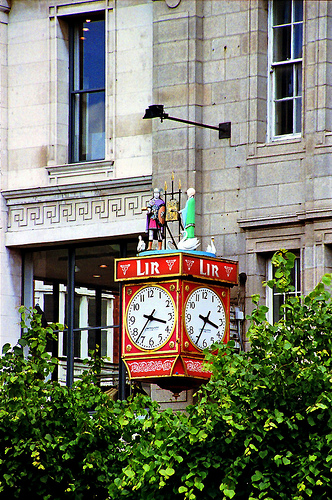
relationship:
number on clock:
[165, 310, 174, 320] [105, 242, 246, 409]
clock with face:
[116, 282, 233, 358] [112, 244, 238, 386]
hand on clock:
[143, 313, 167, 324] [123, 286, 179, 350]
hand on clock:
[134, 308, 153, 343] [123, 286, 179, 350]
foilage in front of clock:
[207, 337, 304, 423] [94, 264, 208, 339]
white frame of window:
[264, 259, 276, 335] [250, 243, 308, 362]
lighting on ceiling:
[96, 261, 106, 268] [75, 257, 111, 289]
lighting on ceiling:
[93, 272, 101, 277] [75, 257, 111, 289]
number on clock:
[202, 291, 209, 300] [123, 286, 179, 350]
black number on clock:
[164, 311, 173, 321] [123, 286, 179, 350]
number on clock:
[131, 301, 140, 311] [123, 286, 179, 350]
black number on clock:
[139, 291, 148, 305] [123, 286, 179, 350]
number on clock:
[188, 325, 194, 333] [183, 286, 226, 350]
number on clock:
[202, 291, 209, 300] [183, 282, 228, 359]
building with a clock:
[151, 6, 331, 405] [117, 246, 239, 377]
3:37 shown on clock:
[123, 287, 168, 345] [115, 246, 235, 399]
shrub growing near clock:
[1, 303, 66, 414] [112, 170, 239, 398]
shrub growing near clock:
[109, 407, 212, 498] [112, 170, 239, 398]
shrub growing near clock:
[184, 246, 321, 436] [112, 170, 239, 398]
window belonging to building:
[42, 2, 121, 177] [1, 2, 279, 389]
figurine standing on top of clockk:
[146, 186, 165, 249] [122, 254, 238, 364]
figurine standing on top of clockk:
[135, 232, 145, 251] [122, 254, 238, 364]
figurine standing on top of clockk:
[176, 186, 196, 252] [122, 254, 238, 364]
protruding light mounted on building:
[141, 103, 231, 139] [0, 0, 331, 411]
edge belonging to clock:
[114, 285, 127, 362] [125, 285, 175, 352]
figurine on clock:
[176, 186, 197, 252] [117, 246, 239, 377]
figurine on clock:
[144, 186, 167, 250] [117, 246, 239, 377]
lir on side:
[135, 257, 159, 277] [111, 255, 179, 380]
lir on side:
[198, 258, 220, 277] [179, 251, 236, 377]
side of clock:
[179, 251, 236, 377] [117, 246, 239, 377]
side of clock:
[111, 255, 179, 380] [117, 246, 239, 377]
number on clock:
[143, 288, 153, 298] [117, 246, 239, 377]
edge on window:
[44, 55, 94, 152] [49, 4, 134, 164]